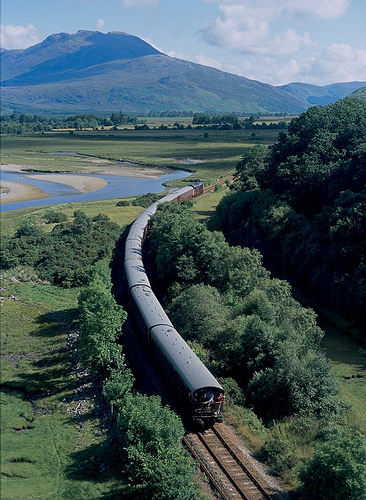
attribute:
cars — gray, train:
[143, 326, 232, 431]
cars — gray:
[123, 284, 181, 351]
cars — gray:
[119, 255, 157, 303]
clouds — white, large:
[1, 21, 44, 55]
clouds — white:
[199, 4, 310, 60]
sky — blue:
[1, 2, 364, 86]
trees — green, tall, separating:
[143, 199, 365, 421]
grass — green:
[1, 192, 216, 500]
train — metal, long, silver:
[121, 182, 233, 429]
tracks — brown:
[128, 165, 279, 500]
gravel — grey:
[62, 323, 101, 433]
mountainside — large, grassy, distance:
[1, 23, 365, 126]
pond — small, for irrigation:
[1, 151, 198, 222]